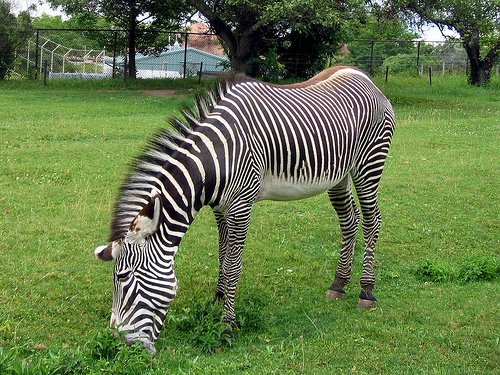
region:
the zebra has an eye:
[113, 269, 138, 284]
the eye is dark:
[113, 265, 133, 285]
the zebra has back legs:
[326, 191, 383, 312]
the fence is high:
[40, 41, 86, 83]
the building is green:
[138, 43, 221, 76]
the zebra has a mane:
[132, 117, 188, 152]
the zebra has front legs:
[211, 230, 251, 346]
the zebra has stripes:
[279, 106, 338, 156]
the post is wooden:
[424, 66, 442, 94]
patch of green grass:
[421, 241, 498, 327]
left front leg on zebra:
[225, 220, 241, 340]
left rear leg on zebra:
[357, 180, 382, 306]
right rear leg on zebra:
[328, 185, 355, 303]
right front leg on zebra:
[212, 205, 223, 306]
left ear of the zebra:
[129, 197, 164, 235]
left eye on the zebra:
[112, 267, 135, 284]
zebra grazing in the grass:
[94, 61, 401, 344]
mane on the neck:
[106, 83, 220, 234]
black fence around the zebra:
[0, 27, 193, 82]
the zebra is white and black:
[103, 71, 401, 357]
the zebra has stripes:
[98, 52, 399, 357]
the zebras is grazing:
[98, 238, 168, 359]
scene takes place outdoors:
[1, 0, 498, 372]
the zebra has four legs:
[203, 182, 380, 339]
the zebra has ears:
[96, 194, 161, 260]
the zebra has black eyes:
[116, 269, 128, 281]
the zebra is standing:
[104, 63, 397, 355]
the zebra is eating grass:
[103, 190, 177, 366]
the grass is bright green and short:
[1, 74, 496, 371]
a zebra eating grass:
[57, 51, 431, 358]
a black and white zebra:
[65, 46, 443, 368]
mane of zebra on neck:
[73, 87, 210, 244]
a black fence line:
[28, 14, 485, 104]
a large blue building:
[93, 40, 243, 99]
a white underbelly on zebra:
[253, 174, 349, 211]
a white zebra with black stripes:
[76, 56, 461, 368]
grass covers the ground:
[9, 83, 499, 373]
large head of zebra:
[68, 217, 223, 368]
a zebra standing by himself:
[49, 34, 429, 350]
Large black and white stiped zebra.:
[93, 63, 396, 359]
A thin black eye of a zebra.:
[116, 269, 132, 279]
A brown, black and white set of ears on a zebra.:
[94, 194, 161, 260]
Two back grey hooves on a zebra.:
[325, 287, 377, 312]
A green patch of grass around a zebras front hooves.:
[182, 286, 265, 347]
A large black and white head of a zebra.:
[106, 238, 177, 358]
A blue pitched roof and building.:
[101, 44, 231, 74]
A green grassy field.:
[4, 78, 497, 371]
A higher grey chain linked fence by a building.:
[6, 24, 106, 79]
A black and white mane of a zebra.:
[102, 74, 244, 244]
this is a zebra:
[72, 28, 460, 370]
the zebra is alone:
[46, 22, 471, 373]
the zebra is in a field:
[35, 27, 454, 365]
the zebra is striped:
[18, 34, 443, 370]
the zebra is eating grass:
[74, 33, 430, 369]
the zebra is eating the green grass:
[51, 20, 485, 372]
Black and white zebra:
[86, 65, 396, 355]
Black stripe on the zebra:
[156, 169, 193, 226]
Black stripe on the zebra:
[194, 125, 228, 208]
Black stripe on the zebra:
[200, 114, 232, 201]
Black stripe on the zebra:
[235, 83, 282, 178]